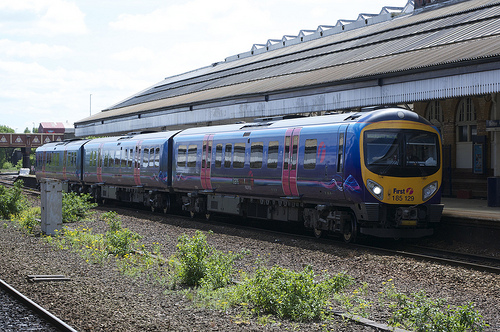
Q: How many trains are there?
A: One.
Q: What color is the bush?
A: Green.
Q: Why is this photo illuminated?
A: Sunlight.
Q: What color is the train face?
A: Yellow.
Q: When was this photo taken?
A: During the day.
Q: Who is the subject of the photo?
A: The train.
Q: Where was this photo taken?
A: At the train station.